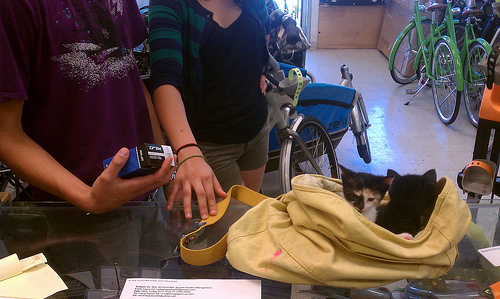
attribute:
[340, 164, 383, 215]
kitten — black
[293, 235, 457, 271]
backpack — yellow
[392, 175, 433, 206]
kitten — black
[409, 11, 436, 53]
bicycle — green, inside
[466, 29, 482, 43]
bicycle — green, inside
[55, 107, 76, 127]
shirt — purple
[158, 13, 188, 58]
sweater — striped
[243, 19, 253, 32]
shirt — black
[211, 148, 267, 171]
shorts — brown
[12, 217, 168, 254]
counter top — glass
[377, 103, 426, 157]
floor — white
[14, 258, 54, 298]
paper — white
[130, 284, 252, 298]
paper — white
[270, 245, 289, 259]
smudge — red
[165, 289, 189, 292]
writing — black